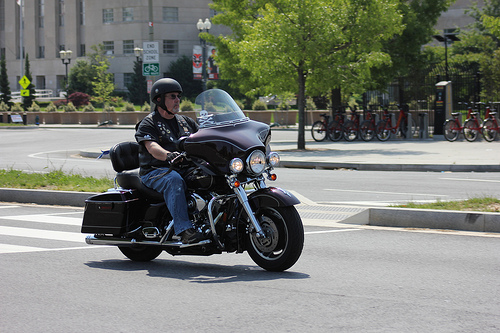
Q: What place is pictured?
A: It is a road.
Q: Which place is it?
A: It is a road.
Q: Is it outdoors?
A: Yes, it is outdoors.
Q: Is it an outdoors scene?
A: Yes, it is outdoors.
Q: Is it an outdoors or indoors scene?
A: It is outdoors.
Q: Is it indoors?
A: No, it is outdoors.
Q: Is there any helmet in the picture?
A: Yes, there is a helmet.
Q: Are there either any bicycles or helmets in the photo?
A: Yes, there is a helmet.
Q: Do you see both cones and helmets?
A: No, there is a helmet but no cones.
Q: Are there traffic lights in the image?
A: No, there are no traffic lights.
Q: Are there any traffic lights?
A: No, there are no traffic lights.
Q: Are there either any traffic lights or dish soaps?
A: No, there are no traffic lights or dish soaps.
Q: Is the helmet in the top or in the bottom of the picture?
A: The helmet is in the top of the image.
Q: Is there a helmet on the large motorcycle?
A: Yes, there is a helmet on the motorcycle.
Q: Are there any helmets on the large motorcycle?
A: Yes, there is a helmet on the motorcycle.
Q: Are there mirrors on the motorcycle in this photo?
A: No, there is a helmet on the motorcycle.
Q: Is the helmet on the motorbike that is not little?
A: Yes, the helmet is on the motorbike.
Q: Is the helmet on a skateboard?
A: No, the helmet is on the motorbike.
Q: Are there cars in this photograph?
A: No, there are no cars.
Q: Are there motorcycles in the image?
A: Yes, there is a motorcycle.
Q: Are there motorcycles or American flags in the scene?
A: Yes, there is a motorcycle.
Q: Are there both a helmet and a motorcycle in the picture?
A: Yes, there are both a motorcycle and a helmet.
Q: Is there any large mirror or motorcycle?
A: Yes, there is a large motorcycle.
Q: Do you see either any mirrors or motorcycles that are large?
A: Yes, the motorcycle is large.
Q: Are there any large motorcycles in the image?
A: Yes, there is a large motorcycle.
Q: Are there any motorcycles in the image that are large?
A: Yes, there is a motorcycle that is large.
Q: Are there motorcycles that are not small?
A: Yes, there is a large motorcycle.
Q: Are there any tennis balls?
A: No, there are no tennis balls.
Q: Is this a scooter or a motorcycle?
A: This is a motorcycle.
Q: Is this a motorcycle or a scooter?
A: This is a motorcycle.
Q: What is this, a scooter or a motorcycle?
A: This is a motorcycle.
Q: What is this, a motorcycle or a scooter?
A: This is a motorcycle.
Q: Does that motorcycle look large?
A: Yes, the motorcycle is large.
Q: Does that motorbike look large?
A: Yes, the motorbike is large.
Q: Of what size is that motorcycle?
A: The motorcycle is large.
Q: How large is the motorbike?
A: The motorbike is large.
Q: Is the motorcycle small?
A: No, the motorcycle is large.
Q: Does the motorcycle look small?
A: No, the motorcycle is large.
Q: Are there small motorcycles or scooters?
A: No, there is a motorcycle but it is large.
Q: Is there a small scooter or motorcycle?
A: No, there is a motorcycle but it is large.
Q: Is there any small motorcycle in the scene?
A: No, there is a motorcycle but it is large.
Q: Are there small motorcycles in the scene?
A: No, there is a motorcycle but it is large.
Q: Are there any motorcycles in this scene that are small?
A: No, there is a motorcycle but it is large.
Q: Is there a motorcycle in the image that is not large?
A: No, there is a motorcycle but it is large.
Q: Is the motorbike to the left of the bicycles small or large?
A: The motorbike is large.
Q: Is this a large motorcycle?
A: Yes, this is a large motorcycle.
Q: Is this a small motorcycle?
A: No, this is a large motorcycle.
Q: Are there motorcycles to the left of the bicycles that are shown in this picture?
A: Yes, there is a motorcycle to the left of the bicycles.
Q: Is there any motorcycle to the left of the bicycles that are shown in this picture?
A: Yes, there is a motorcycle to the left of the bicycles.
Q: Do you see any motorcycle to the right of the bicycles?
A: No, the motorcycle is to the left of the bicycles.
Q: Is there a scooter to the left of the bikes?
A: No, there is a motorcycle to the left of the bikes.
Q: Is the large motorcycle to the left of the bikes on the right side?
A: Yes, the motorcycle is to the left of the bicycles.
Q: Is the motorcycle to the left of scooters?
A: No, the motorcycle is to the left of the bicycles.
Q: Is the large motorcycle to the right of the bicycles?
A: No, the motorbike is to the left of the bicycles.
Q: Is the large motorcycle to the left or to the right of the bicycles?
A: The motorbike is to the left of the bicycles.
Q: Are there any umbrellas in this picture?
A: No, there are no umbrellas.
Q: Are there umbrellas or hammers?
A: No, there are no umbrellas or hammers.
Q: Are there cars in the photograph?
A: No, there are no cars.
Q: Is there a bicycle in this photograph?
A: Yes, there are bicycles.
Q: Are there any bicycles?
A: Yes, there are bicycles.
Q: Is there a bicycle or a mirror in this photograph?
A: Yes, there are bicycles.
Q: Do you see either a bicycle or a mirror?
A: Yes, there are bicycles.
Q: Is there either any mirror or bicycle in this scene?
A: Yes, there are bicycles.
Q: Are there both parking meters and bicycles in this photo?
A: No, there are bicycles but no parking meters.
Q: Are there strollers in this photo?
A: No, there are no strollers.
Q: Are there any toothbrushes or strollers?
A: No, there are no strollers or toothbrushes.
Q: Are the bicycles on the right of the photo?
A: Yes, the bicycles are on the right of the image.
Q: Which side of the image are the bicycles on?
A: The bicycles are on the right of the image.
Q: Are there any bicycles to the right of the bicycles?
A: Yes, there are bicycles to the right of the bicycles.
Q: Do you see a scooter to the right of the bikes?
A: No, there are bicycles to the right of the bikes.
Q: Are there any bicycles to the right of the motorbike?
A: Yes, there are bicycles to the right of the motorbike.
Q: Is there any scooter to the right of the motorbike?
A: No, there are bicycles to the right of the motorbike.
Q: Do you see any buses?
A: No, there are no buses.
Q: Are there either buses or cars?
A: No, there are no buses or cars.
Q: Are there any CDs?
A: No, there are no cds.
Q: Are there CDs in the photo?
A: No, there are no cds.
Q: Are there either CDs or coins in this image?
A: No, there are no CDs or coins.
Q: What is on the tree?
A: The leaves are on the tree.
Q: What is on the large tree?
A: The leaves are on the tree.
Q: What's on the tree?
A: The leaves are on the tree.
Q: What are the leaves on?
A: The leaves are on the tree.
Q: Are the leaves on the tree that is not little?
A: Yes, the leaves are on the tree.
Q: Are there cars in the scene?
A: No, there are no cars.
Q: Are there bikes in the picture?
A: Yes, there are bikes.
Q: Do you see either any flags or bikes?
A: Yes, there are bikes.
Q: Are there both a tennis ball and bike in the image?
A: No, there are bikes but no tennis balls.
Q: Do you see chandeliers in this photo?
A: No, there are no chandeliers.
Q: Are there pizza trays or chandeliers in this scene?
A: No, there are no chandeliers or pizza trays.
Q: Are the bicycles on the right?
A: Yes, the bicycles are on the right of the image.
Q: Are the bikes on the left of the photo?
A: No, the bikes are on the right of the image.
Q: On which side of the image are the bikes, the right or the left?
A: The bikes are on the right of the image.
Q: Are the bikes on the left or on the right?
A: The bikes are on the right of the image.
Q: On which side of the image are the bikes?
A: The bikes are on the right of the image.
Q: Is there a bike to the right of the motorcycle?
A: Yes, there are bikes to the right of the motorcycle.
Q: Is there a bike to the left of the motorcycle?
A: No, the bikes are to the right of the motorcycle.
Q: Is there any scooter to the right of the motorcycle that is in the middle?
A: No, there are bikes to the right of the motorbike.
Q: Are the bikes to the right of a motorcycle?
A: Yes, the bikes are to the right of a motorcycle.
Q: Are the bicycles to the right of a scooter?
A: No, the bicycles are to the right of a motorcycle.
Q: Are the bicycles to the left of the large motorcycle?
A: No, the bicycles are to the right of the motorcycle.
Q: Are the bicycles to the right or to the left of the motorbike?
A: The bicycles are to the right of the motorbike.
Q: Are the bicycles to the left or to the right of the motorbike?
A: The bicycles are to the right of the motorbike.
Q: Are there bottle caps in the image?
A: No, there are no bottle caps.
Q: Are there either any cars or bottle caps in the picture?
A: No, there are no bottle caps or cars.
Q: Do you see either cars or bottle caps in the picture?
A: No, there are no bottle caps or cars.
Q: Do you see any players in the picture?
A: No, there are no players.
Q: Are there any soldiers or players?
A: No, there are no players or soldiers.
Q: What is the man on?
A: The man is on the motorbike.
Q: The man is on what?
A: The man is on the motorbike.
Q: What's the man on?
A: The man is on the motorbike.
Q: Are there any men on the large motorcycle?
A: Yes, there is a man on the motorcycle.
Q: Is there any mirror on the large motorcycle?
A: No, there is a man on the motorcycle.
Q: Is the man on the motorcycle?
A: Yes, the man is on the motorcycle.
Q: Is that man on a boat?
A: No, the man is on the motorcycle.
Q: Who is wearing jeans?
A: The man is wearing jeans.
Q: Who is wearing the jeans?
A: The man is wearing jeans.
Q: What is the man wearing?
A: The man is wearing jeans.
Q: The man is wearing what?
A: The man is wearing jeans.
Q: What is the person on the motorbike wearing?
A: The man is wearing jeans.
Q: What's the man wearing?
A: The man is wearing jeans.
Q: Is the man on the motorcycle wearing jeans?
A: Yes, the man is wearing jeans.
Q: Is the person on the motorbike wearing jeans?
A: Yes, the man is wearing jeans.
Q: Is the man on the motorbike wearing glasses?
A: No, the man is wearing jeans.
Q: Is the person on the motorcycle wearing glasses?
A: No, the man is wearing jeans.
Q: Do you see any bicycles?
A: Yes, there are bicycles.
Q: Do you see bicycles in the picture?
A: Yes, there are bicycles.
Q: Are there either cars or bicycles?
A: Yes, there are bicycles.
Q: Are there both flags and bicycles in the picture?
A: No, there are bicycles but no flags.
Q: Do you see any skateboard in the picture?
A: No, there are no skateboards.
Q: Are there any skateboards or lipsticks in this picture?
A: No, there are no skateboards or lipsticks.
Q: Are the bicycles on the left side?
A: No, the bicycles are on the right of the image.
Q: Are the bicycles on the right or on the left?
A: The bicycles are on the right of the image.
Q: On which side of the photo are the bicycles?
A: The bicycles are on the right of the image.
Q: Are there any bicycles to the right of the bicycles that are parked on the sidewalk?
A: Yes, there are bicycles to the right of the bikes.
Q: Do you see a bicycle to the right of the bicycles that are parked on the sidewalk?
A: Yes, there are bicycles to the right of the bikes.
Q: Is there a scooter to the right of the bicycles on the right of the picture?
A: No, there are bicycles to the right of the bicycles.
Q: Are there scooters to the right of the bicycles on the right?
A: No, there are bicycles to the right of the bicycles.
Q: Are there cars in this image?
A: No, there are no cars.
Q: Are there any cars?
A: No, there are no cars.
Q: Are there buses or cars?
A: No, there are no cars or buses.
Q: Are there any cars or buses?
A: No, there are no cars or buses.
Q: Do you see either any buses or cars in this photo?
A: No, there are no cars or buses.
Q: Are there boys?
A: No, there are no boys.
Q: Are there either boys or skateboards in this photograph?
A: No, there are no boys or skateboards.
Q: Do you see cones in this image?
A: No, there are no cones.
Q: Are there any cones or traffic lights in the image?
A: No, there are no cones or traffic lights.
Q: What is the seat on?
A: The seat is on the motorbike.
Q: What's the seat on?
A: The seat is on the motorbike.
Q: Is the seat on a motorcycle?
A: Yes, the seat is on a motorcycle.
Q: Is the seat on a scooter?
A: No, the seat is on a motorcycle.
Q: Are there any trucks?
A: No, there are no trucks.